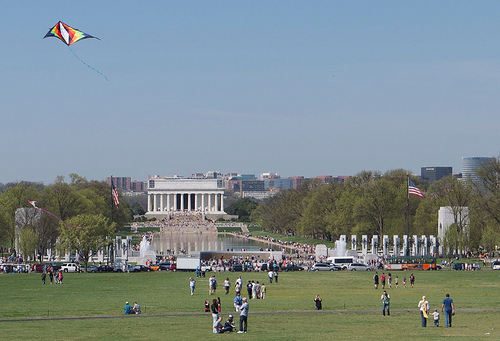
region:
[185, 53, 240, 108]
white clouds in blue sky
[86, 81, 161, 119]
white clouds in blue sky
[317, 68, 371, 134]
white clouds in blue sky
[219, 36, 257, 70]
white clouds in blue sky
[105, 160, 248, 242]
the washington monument in the background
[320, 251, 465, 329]
people are walking on the grass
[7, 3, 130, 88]
the kite is multi colored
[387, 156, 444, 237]
the flag is on a pole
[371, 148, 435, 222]
the flag is blowing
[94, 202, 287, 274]
the water is calm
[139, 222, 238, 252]
the water is reflecting the monument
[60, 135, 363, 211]
buildings in the background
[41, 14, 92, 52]
kite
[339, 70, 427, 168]
white clouds in blue sky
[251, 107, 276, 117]
white clouds in blue sky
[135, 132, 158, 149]
white clouds in blue sky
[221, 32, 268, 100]
white clouds in blue sky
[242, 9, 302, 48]
white clouds in blue sky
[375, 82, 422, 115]
white clouds in blue sky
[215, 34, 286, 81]
white clouds in blue sky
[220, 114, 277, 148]
white clouds in blue sky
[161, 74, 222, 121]
white clouds in blue sky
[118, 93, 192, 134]
white clouds in blue sky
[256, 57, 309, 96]
white clouds in blue sky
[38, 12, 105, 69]
a colorful kite in the sky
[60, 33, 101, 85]
the tail of a kite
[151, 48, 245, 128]
a clear and blue sky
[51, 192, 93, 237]
a bunch of bright green trees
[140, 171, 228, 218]
the front of a federal building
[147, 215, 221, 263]
a large still water fountain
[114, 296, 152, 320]
a couple sitting in the grass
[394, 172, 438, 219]
the american flag flying in the sky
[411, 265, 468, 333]
a small family of three